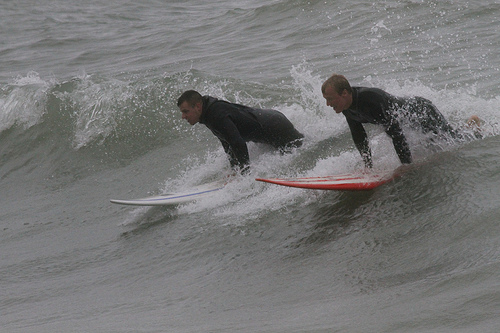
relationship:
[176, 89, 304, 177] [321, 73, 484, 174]
man surfing with surfer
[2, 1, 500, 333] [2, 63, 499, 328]
ocean has wave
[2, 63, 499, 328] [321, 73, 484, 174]
wave crashing into surfer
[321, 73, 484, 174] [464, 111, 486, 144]
surfer has foot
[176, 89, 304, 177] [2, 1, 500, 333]
man out in ocean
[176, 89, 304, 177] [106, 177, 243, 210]
man on top of surfboard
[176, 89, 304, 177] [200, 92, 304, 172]
man wearing wet suit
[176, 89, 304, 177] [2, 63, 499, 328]
man on top of wave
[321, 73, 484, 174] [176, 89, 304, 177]
surfer teaching man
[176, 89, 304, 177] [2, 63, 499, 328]
man catching wave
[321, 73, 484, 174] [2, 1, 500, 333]
surfer in ocean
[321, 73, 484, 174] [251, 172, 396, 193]
surfer kneeling on surfboard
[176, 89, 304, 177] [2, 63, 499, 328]
man ride wave